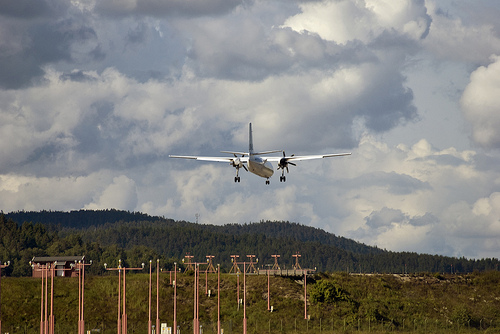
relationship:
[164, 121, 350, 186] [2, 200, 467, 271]
plane landing in mountains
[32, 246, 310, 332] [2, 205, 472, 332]
power lines in mountainous terrain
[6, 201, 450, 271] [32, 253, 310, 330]
green mountains behind power lines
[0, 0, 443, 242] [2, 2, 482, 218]
dark clouds in sky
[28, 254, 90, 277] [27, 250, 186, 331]
building behind power lines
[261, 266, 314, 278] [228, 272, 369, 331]
small bridge at top of hill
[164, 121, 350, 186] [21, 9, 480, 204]
plane in air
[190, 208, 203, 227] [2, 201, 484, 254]
tower in distance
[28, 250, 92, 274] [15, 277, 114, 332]
building on a hill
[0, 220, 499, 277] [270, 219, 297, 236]
hill covered in trees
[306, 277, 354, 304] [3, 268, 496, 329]
bush on hill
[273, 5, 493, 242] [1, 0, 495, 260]
clouds in sky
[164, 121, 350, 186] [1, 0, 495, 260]
plane in sky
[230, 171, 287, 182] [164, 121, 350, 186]
landing gear on plane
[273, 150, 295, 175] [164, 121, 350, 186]
propeller on plane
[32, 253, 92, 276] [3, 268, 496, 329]
house on hill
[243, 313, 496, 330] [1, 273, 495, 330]
fencing along ground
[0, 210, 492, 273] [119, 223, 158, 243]
mountains covered in trees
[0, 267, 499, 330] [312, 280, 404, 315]
hills have trees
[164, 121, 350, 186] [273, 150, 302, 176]
plane has propellers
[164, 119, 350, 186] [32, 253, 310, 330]
plane flying above power lines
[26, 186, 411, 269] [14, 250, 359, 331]
hill beyond approach lights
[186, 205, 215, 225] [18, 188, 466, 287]
communication tower above hill